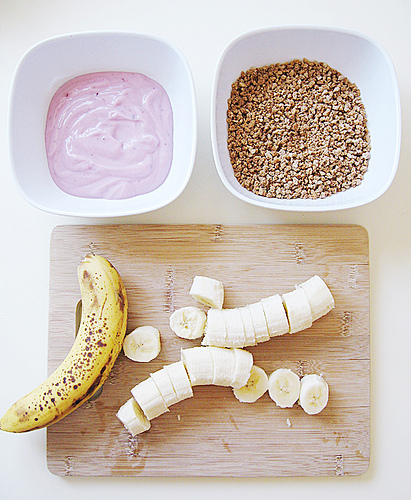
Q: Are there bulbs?
A: No, there are no bulbs.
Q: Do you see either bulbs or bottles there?
A: No, there are no bulbs or bottles.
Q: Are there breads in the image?
A: No, there are no breads.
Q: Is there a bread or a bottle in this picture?
A: No, there are no breads or bottles.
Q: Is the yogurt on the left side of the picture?
A: Yes, the yogurt is on the left of the image.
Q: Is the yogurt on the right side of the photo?
A: No, the yogurt is on the left of the image.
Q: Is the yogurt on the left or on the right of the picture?
A: The yogurt is on the left of the image.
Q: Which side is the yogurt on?
A: The yogurt is on the left of the image.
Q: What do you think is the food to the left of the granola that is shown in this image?
A: The food is yogurt.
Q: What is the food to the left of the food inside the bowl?
A: The food is yogurt.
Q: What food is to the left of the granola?
A: The food is yogurt.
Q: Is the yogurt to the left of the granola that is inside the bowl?
A: Yes, the yogurt is to the left of the granola.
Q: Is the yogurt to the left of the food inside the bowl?
A: Yes, the yogurt is to the left of the granola.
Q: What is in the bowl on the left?
A: The yogurt is in the bowl.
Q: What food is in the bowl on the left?
A: The food is yogurt.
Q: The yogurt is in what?
A: The yogurt is in the bowl.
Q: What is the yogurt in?
A: The yogurt is in the bowl.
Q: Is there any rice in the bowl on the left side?
A: No, there is yogurt in the bowl.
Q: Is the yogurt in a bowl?
A: Yes, the yogurt is in a bowl.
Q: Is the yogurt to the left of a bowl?
A: Yes, the yogurt is to the left of a bowl.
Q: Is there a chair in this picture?
A: No, there are no chairs.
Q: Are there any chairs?
A: No, there are no chairs.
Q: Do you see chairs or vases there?
A: No, there are no chairs or vases.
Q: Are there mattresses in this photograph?
A: No, there are no mattresses.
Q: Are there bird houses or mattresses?
A: No, there are no mattresses or bird houses.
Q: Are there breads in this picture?
A: No, there are no breads.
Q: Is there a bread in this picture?
A: No, there is no breads.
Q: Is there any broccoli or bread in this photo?
A: No, there are no breads or broccoli.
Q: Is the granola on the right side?
A: Yes, the granola is on the right of the image.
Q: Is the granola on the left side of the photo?
A: No, the granola is on the right of the image.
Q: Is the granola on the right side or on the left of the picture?
A: The granola is on the right of the image.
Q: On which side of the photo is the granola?
A: The granola is on the right of the image.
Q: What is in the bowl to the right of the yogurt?
A: The granola is in the bowl.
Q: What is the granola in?
A: The granola is in the bowl.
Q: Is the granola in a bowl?
A: Yes, the granola is in a bowl.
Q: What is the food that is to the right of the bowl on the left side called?
A: The food is granola.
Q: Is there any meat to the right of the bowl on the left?
A: No, there is granola to the right of the bowl.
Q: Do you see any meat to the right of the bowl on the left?
A: No, there is granola to the right of the bowl.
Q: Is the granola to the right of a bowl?
A: Yes, the granola is to the right of a bowl.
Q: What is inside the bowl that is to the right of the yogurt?
A: The granola is inside the bowl.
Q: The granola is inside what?
A: The granola is inside the bowl.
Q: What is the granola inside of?
A: The granola is inside the bowl.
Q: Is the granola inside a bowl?
A: Yes, the granola is inside a bowl.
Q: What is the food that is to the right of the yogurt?
A: The food is granola.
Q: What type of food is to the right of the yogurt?
A: The food is granola.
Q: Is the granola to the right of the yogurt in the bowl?
A: Yes, the granola is to the right of the yogurt.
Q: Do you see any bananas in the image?
A: Yes, there is a banana.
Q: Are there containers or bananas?
A: Yes, there is a banana.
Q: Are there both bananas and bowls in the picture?
A: Yes, there are both a banana and a bowl.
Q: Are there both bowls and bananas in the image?
A: Yes, there are both a banana and a bowl.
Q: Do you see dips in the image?
A: No, there are no dips.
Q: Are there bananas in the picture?
A: Yes, there is a banana.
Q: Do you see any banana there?
A: Yes, there is a banana.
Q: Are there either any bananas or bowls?
A: Yes, there is a banana.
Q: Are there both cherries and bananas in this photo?
A: No, there is a banana but no cherries.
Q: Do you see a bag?
A: No, there are no bags.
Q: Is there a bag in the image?
A: No, there are no bags.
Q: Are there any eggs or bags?
A: No, there are no bags or eggs.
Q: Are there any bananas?
A: Yes, there is a banana.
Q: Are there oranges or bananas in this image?
A: Yes, there is a banana.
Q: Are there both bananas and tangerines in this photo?
A: No, there is a banana but no tangerines.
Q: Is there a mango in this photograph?
A: No, there are no mangoes.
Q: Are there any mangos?
A: No, there are no mangos.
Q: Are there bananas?
A: Yes, there is a banana.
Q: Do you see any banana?
A: Yes, there is a banana.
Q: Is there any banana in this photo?
A: Yes, there is a banana.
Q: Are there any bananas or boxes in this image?
A: Yes, there is a banana.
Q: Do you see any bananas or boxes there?
A: Yes, there is a banana.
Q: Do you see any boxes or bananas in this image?
A: Yes, there is a banana.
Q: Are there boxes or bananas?
A: Yes, there is a banana.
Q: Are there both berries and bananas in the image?
A: No, there is a banana but no berries.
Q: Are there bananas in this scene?
A: Yes, there is a banana.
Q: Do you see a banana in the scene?
A: Yes, there is a banana.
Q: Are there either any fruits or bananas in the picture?
A: Yes, there is a banana.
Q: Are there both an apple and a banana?
A: No, there is a banana but no apples.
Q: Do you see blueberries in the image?
A: No, there are no blueberries.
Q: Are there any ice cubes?
A: No, there are no ice cubes.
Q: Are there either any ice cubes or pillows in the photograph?
A: No, there are no ice cubes or pillows.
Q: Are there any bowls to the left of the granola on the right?
A: Yes, there is a bowl to the left of the granola.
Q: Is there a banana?
A: Yes, there is a banana.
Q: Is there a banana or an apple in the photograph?
A: Yes, there is a banana.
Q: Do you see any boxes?
A: No, there are no boxes.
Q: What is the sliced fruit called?
A: The fruit is a banana.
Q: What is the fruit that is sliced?
A: The fruit is a banana.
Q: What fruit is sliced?
A: The fruit is a banana.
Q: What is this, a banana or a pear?
A: This is a banana.